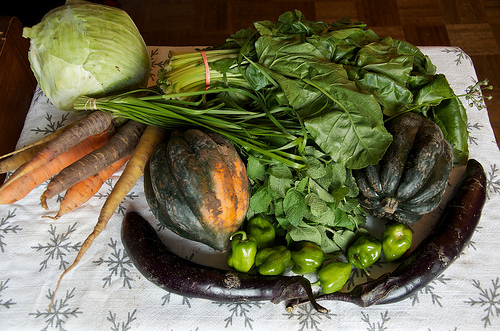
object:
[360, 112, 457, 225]
squash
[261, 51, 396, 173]
green leaf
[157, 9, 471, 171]
bunch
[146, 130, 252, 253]
corn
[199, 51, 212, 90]
pink band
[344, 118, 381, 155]
ground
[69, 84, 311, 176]
stock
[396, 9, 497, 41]
wood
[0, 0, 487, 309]
vegetable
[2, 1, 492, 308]
produce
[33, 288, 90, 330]
design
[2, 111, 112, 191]
carrots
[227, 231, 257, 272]
bonnet pepper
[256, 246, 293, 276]
bonnet pepper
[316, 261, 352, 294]
bonnet pepper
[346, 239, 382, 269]
bonnet pepper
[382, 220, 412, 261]
bonnet pepper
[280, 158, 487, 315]
eggplant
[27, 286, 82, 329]
snow flake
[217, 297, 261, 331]
snow flake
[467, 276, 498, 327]
snow flake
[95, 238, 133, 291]
snow flake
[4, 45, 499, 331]
sheet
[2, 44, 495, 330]
table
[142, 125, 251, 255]
squash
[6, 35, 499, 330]
towel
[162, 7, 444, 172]
lettuce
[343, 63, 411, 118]
green leaves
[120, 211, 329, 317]
eggplant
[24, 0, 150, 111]
cabbage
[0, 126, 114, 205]
carrot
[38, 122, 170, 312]
carrot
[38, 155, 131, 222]
carrot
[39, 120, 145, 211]
carrot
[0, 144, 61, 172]
carrots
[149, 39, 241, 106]
stock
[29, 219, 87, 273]
snowflake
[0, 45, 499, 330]
cloth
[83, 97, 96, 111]
band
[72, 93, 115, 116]
stems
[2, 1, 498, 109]
floor